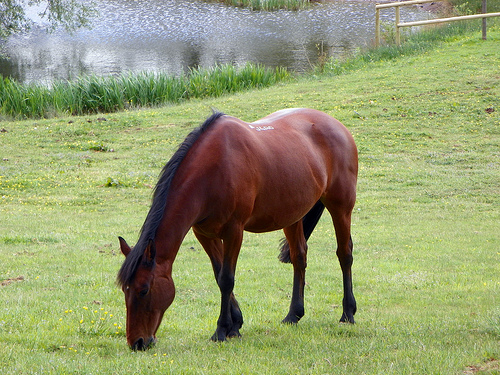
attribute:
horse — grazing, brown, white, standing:
[114, 105, 360, 352]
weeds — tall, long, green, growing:
[0, 62, 291, 121]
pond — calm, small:
[0, 0, 440, 84]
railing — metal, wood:
[374, 0, 499, 54]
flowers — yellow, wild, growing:
[57, 304, 175, 369]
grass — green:
[0, 16, 499, 374]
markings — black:
[207, 256, 356, 341]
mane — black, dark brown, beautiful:
[117, 109, 222, 286]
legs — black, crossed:
[195, 180, 357, 341]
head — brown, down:
[122, 249, 176, 351]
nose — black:
[129, 335, 158, 349]